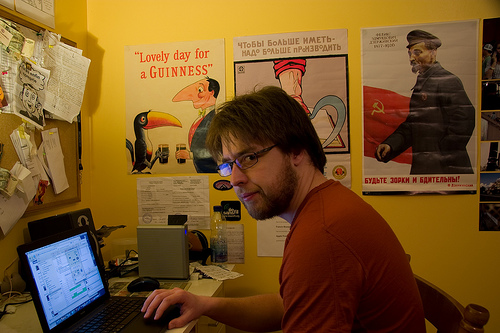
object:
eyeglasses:
[216, 140, 292, 176]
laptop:
[14, 230, 186, 333]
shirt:
[278, 179, 416, 327]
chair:
[405, 254, 493, 333]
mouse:
[126, 276, 160, 291]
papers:
[44, 42, 93, 123]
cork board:
[0, 56, 82, 217]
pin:
[36, 32, 42, 36]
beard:
[237, 156, 298, 219]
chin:
[245, 207, 278, 221]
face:
[213, 127, 287, 219]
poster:
[360, 20, 478, 198]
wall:
[134, 0, 356, 27]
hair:
[203, 81, 330, 174]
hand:
[140, 287, 207, 329]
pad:
[109, 282, 192, 297]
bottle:
[209, 205, 228, 266]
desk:
[0, 263, 238, 333]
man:
[137, 84, 426, 333]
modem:
[135, 226, 190, 281]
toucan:
[125, 109, 183, 175]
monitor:
[24, 232, 106, 330]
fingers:
[144, 288, 178, 318]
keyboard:
[71, 297, 149, 333]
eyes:
[241, 154, 258, 164]